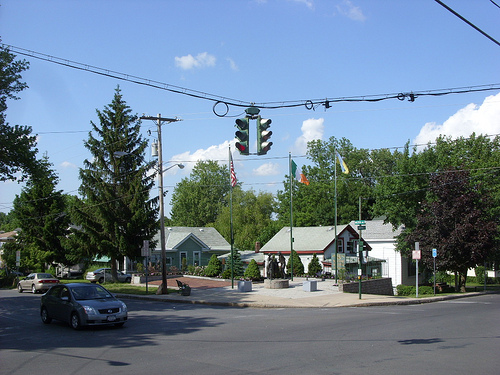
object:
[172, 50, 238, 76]
cloud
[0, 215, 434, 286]
houses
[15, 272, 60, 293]
car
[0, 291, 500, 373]
road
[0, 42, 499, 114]
wire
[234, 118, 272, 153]
signals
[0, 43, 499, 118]
cable set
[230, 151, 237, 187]
flag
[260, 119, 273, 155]
traffic light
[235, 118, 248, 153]
traffic light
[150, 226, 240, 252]
roof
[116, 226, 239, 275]
house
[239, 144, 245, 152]
red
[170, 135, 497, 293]
trees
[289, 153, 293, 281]
pole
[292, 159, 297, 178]
flag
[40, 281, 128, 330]
car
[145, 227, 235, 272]
building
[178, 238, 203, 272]
wall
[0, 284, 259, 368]
shadow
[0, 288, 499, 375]
ground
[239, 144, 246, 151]
light